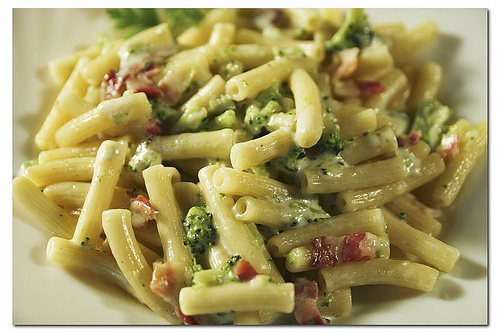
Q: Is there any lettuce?
A: No, there is no lettuce.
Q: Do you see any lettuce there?
A: No, there is no lettuce.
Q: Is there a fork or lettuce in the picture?
A: No, there are no lettuce or forks.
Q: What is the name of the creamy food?
A: The food is pasta salad.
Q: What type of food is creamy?
A: The food is pasta salad.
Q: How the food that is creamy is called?
A: The food is pasta salad.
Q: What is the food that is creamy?
A: The food is pasta salad.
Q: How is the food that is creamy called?
A: The food is pasta salad.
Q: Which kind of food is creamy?
A: The food is pasta salad.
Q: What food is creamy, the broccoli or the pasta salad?
A: The pasta salad is creamy.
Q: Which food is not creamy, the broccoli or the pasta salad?
A: The broccoli is not creamy.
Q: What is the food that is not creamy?
A: The food is broccoli.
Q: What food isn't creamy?
A: The food is broccoli.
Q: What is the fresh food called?
A: The food is pasta salad.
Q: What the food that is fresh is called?
A: The food is pasta salad.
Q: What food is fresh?
A: The food is pasta salad.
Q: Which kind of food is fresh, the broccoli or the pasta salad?
A: The pasta salad is fresh.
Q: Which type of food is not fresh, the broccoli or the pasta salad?
A: The broccoli is not fresh.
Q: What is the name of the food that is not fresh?
A: The food is broccoli.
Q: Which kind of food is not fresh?
A: The food is broccoli.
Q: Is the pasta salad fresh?
A: Yes, the pasta salad is fresh.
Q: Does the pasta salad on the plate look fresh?
A: Yes, the pasta salad is fresh.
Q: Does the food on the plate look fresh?
A: Yes, the pasta salad is fresh.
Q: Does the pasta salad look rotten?
A: No, the pasta salad is fresh.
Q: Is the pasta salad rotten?
A: No, the pasta salad is fresh.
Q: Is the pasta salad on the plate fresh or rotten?
A: The pasta salad is fresh.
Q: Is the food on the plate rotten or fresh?
A: The pasta salad is fresh.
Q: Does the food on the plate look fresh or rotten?
A: The pasta salad is fresh.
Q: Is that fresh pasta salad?
A: Yes, that is fresh pasta salad.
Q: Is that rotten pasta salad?
A: No, that is fresh pasta salad.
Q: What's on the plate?
A: The pasta salad is on the plate.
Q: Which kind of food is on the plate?
A: The food is pasta salad.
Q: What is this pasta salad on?
A: The pasta salad is on the plate.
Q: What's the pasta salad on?
A: The pasta salad is on the plate.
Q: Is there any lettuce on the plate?
A: No, there is pasta salad on the plate.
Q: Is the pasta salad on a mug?
A: No, the pasta salad is on the plate.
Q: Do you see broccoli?
A: Yes, there is broccoli.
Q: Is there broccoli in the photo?
A: Yes, there is broccoli.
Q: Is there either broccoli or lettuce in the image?
A: Yes, there is broccoli.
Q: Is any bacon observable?
A: Yes, there is bacon.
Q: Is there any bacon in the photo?
A: Yes, there is bacon.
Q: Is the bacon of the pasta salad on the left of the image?
A: Yes, the bacon is on the left of the image.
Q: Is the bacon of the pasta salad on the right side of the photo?
A: No, the bacon is on the left of the image.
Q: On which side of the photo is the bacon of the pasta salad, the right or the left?
A: The bacon is on the left of the image.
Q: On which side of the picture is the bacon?
A: The bacon is on the left of the image.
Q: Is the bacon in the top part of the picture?
A: Yes, the bacon is in the top of the image.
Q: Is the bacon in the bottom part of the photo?
A: No, the bacon is in the top of the image.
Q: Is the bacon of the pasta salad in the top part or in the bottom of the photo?
A: The bacon is in the top of the image.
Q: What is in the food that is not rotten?
A: The bacon is in the pasta salad.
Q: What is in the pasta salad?
A: The bacon is in the pasta salad.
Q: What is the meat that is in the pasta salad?
A: The meat is bacon.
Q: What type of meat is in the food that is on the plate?
A: The meat is bacon.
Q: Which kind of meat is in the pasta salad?
A: The meat is bacon.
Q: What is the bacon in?
A: The bacon is in the pasta salad.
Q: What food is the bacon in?
A: The bacon is in the pasta salad.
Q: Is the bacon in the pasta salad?
A: Yes, the bacon is in the pasta salad.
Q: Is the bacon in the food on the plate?
A: Yes, the bacon is in the pasta salad.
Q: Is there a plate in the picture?
A: Yes, there is a plate.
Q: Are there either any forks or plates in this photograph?
A: Yes, there is a plate.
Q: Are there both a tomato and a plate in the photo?
A: No, there is a plate but no tomatoes.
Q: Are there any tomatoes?
A: No, there are no tomatoes.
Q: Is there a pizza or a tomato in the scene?
A: No, there are no tomatoes or pizzas.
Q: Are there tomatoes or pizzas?
A: No, there are no tomatoes or pizzas.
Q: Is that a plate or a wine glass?
A: That is a plate.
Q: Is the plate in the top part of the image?
A: No, the plate is in the bottom of the image.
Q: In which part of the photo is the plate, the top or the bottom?
A: The plate is in the bottom of the image.